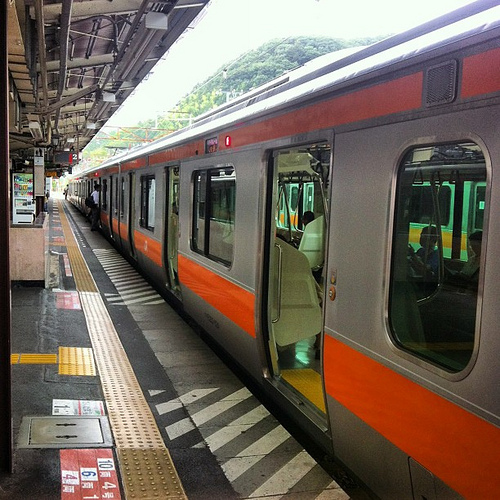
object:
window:
[388, 139, 487, 374]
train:
[68, 0, 500, 499]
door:
[268, 139, 332, 440]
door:
[162, 165, 182, 302]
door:
[128, 171, 137, 261]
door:
[109, 175, 115, 240]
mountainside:
[72, 35, 398, 176]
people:
[408, 226, 483, 278]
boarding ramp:
[48, 198, 348, 499]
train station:
[0, 0, 500, 498]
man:
[301, 210, 315, 226]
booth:
[8, 172, 49, 287]